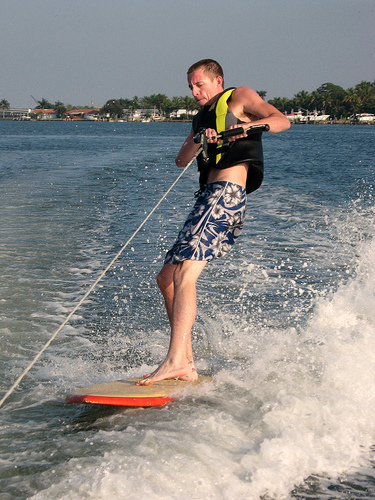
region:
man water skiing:
[107, 48, 279, 405]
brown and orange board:
[77, 378, 140, 421]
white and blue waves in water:
[256, 328, 287, 360]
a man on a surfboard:
[126, 78, 322, 399]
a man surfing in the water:
[144, 60, 303, 271]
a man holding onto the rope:
[133, 34, 280, 215]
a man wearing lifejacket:
[149, 48, 269, 238]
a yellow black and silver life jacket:
[185, 82, 297, 180]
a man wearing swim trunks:
[153, 175, 256, 290]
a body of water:
[40, 196, 358, 463]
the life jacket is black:
[181, 88, 276, 201]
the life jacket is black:
[185, 87, 258, 195]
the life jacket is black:
[173, 100, 274, 210]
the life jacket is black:
[177, 86, 261, 179]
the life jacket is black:
[187, 92, 256, 178]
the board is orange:
[56, 362, 224, 434]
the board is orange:
[62, 366, 209, 426]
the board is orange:
[67, 360, 216, 431]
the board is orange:
[57, 360, 235, 457]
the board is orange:
[64, 362, 216, 445]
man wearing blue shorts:
[160, 173, 246, 286]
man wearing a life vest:
[185, 97, 267, 173]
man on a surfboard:
[84, 339, 228, 414]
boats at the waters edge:
[279, 98, 370, 139]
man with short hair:
[179, 52, 231, 99]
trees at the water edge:
[54, 97, 66, 118]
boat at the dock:
[346, 111, 372, 125]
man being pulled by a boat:
[187, 107, 308, 158]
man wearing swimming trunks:
[155, 167, 253, 269]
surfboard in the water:
[68, 385, 176, 424]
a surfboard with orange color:
[61, 358, 221, 408]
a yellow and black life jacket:
[186, 87, 269, 196]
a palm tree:
[344, 87, 361, 119]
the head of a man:
[186, 57, 225, 107]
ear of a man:
[215, 74, 224, 87]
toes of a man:
[133, 378, 153, 388]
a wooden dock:
[319, 118, 358, 124]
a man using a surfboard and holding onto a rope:
[63, 57, 292, 408]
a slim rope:
[0, 142, 205, 407]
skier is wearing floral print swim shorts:
[156, 174, 258, 275]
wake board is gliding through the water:
[60, 350, 279, 416]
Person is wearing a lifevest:
[165, 80, 288, 198]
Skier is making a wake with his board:
[73, 138, 371, 497]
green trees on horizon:
[1, 81, 371, 121]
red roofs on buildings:
[34, 107, 97, 119]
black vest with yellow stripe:
[192, 87, 264, 192]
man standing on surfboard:
[66, 57, 290, 406]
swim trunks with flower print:
[165, 181, 249, 263]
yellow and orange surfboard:
[65, 374, 207, 406]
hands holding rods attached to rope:
[1, 122, 268, 405]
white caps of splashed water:
[2, 179, 373, 498]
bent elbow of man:
[229, 87, 290, 139]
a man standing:
[155, 58, 272, 379]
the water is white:
[172, 453, 214, 489]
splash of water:
[327, 206, 354, 242]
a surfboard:
[80, 378, 142, 414]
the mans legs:
[171, 289, 200, 365]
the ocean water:
[168, 453, 222, 487]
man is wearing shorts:
[194, 186, 241, 263]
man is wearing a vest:
[201, 106, 231, 124]